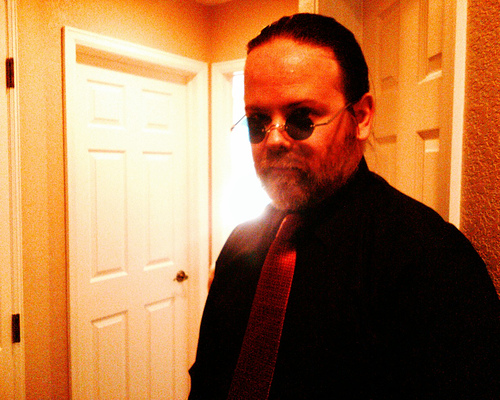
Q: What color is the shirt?
A: Black.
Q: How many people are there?
A: One.